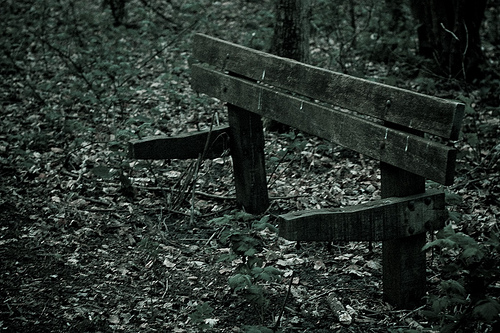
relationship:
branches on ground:
[51, 76, 441, 331] [0, 0, 497, 332]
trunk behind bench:
[268, 0, 313, 67] [126, 32, 468, 300]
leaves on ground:
[174, 208, 272, 330] [32, 72, 184, 306]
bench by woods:
[126, 32, 468, 300] [8, 9, 495, 314]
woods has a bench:
[8, 9, 495, 314] [126, 32, 468, 300]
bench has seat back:
[126, 32, 468, 300] [189, 28, 466, 186]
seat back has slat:
[189, 28, 466, 186] [190, 63, 457, 187]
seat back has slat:
[189, 28, 466, 186] [189, 31, 465, 144]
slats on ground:
[190, 32, 465, 140] [1, 130, 498, 331]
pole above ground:
[212, 87, 279, 239] [0, 0, 497, 332]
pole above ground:
[378, 116, 430, 311] [0, 0, 497, 332]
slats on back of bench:
[191, 30, 465, 140] [126, 32, 468, 300]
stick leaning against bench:
[151, 107, 216, 220] [126, 32, 468, 300]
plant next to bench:
[419, 214, 499, 331] [126, 32, 468, 300]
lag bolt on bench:
[380, 93, 393, 110] [126, 32, 468, 300]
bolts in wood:
[378, 96, 392, 114] [178, 31, 459, 179]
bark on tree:
[275, 19, 327, 66] [398, 2, 489, 76]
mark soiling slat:
[249, 58, 280, 84] [189, 31, 465, 144]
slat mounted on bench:
[189, 31, 465, 144] [126, 32, 468, 300]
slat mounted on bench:
[190, 63, 457, 187] [126, 32, 468, 300]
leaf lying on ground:
[160, 258, 178, 269] [0, 0, 497, 332]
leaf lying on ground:
[162, 167, 182, 180] [0, 0, 497, 332]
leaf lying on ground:
[187, 259, 206, 267] [0, 0, 497, 332]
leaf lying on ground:
[67, 257, 78, 264] [0, 0, 497, 332]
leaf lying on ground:
[122, 200, 133, 206] [0, 0, 497, 332]